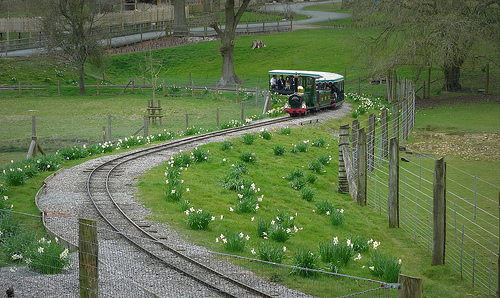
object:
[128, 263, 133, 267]
gravel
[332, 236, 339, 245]
flower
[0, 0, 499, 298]
ground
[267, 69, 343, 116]
train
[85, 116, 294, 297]
train tracks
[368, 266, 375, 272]
flowers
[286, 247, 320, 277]
grass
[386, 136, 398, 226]
post